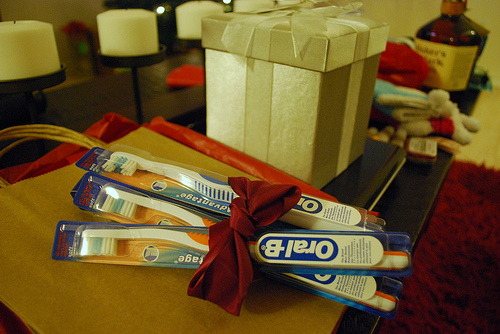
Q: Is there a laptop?
A: Yes, there is a laptop.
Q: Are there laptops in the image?
A: Yes, there is a laptop.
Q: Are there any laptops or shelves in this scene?
A: Yes, there is a laptop.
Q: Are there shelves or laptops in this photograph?
A: Yes, there is a laptop.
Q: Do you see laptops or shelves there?
A: Yes, there is a laptop.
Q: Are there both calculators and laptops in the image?
A: No, there is a laptop but no calculators.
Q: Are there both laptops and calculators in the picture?
A: No, there is a laptop but no calculators.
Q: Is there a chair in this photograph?
A: No, there are no chairs.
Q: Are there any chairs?
A: No, there are no chairs.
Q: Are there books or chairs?
A: No, there are no chairs or books.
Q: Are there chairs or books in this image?
A: No, there are no chairs or books.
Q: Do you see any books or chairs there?
A: No, there are no chairs or books.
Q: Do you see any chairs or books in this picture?
A: No, there are no chairs or books.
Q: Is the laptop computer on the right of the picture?
A: Yes, the laptop computer is on the right of the image.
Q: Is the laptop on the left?
A: No, the laptop is on the right of the image.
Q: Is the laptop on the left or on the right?
A: The laptop is on the right of the image.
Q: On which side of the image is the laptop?
A: The laptop is on the right of the image.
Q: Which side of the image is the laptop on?
A: The laptop is on the right of the image.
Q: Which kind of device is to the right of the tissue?
A: The device is a laptop.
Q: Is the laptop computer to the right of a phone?
A: No, the laptop computer is to the right of the tissue.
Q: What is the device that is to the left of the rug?
A: The device is a laptop.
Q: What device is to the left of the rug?
A: The device is a laptop.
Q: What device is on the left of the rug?
A: The device is a laptop.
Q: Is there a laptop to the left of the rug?
A: Yes, there is a laptop to the left of the rug.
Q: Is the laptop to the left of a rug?
A: Yes, the laptop is to the left of a rug.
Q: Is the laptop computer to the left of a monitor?
A: No, the laptop computer is to the left of a rug.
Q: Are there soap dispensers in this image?
A: No, there are no soap dispensers.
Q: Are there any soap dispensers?
A: No, there are no soap dispensers.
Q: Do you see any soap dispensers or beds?
A: No, there are no soap dispensers or beds.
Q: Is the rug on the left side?
A: No, the rug is on the right of the image.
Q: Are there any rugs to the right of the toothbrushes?
A: Yes, there is a rug to the right of the toothbrushes.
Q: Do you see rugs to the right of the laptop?
A: Yes, there is a rug to the right of the laptop.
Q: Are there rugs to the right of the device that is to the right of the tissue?
A: Yes, there is a rug to the right of the laptop.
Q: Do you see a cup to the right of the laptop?
A: No, there is a rug to the right of the laptop.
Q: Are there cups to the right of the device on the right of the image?
A: No, there is a rug to the right of the laptop.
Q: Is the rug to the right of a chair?
A: No, the rug is to the right of the laptop computer.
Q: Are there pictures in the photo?
A: No, there are no pictures.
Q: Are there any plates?
A: No, there are no plates.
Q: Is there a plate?
A: No, there are no plates.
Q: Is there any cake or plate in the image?
A: No, there are no plates or cakes.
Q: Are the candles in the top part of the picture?
A: Yes, the candles are in the top of the image.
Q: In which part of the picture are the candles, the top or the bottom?
A: The candles are in the top of the image.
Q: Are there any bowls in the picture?
A: No, there are no bowls.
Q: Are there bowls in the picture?
A: No, there are no bowls.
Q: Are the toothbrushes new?
A: Yes, the toothbrushes are new.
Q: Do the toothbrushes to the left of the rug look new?
A: Yes, the toothbrushes are new.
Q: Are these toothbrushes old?
A: No, the toothbrushes are new.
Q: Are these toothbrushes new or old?
A: The toothbrushes are new.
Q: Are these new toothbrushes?
A: Yes, these are new toothbrushes.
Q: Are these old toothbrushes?
A: No, these are new toothbrushes.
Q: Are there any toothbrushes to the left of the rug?
A: Yes, there are toothbrushes to the left of the rug.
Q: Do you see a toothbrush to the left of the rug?
A: Yes, there are toothbrushes to the left of the rug.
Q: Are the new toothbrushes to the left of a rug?
A: Yes, the toothbrushes are to the left of a rug.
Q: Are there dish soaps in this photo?
A: No, there are no dish soaps.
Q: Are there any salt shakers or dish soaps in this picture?
A: No, there are no dish soaps or salt shakers.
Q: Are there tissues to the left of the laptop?
A: Yes, there is a tissue to the left of the laptop.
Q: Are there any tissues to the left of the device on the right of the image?
A: Yes, there is a tissue to the left of the laptop.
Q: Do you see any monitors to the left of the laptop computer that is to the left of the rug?
A: No, there is a tissue to the left of the laptop.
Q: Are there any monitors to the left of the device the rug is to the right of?
A: No, there is a tissue to the left of the laptop.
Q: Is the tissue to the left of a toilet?
A: No, the tissue is to the left of the laptop.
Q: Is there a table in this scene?
A: Yes, there is a table.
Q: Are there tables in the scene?
A: Yes, there is a table.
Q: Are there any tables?
A: Yes, there is a table.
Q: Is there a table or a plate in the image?
A: Yes, there is a table.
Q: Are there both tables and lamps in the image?
A: No, there is a table but no lamps.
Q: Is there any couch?
A: No, there are no couches.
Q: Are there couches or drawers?
A: No, there are no couches or drawers.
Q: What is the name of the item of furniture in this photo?
A: The piece of furniture is a table.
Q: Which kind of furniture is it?
A: The piece of furniture is a table.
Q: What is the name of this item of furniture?
A: This is a table.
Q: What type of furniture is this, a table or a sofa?
A: This is a table.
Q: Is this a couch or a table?
A: This is a table.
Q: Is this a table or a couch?
A: This is a table.